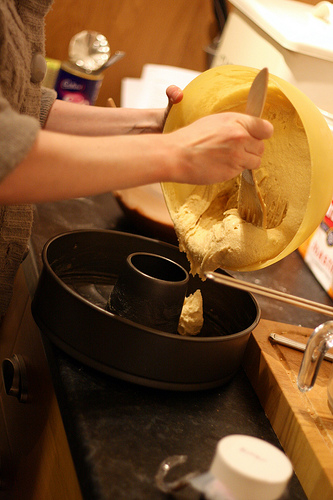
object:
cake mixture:
[173, 85, 311, 334]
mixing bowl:
[158, 61, 332, 272]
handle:
[296, 317, 332, 392]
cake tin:
[30, 227, 262, 394]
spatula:
[236, 66, 269, 231]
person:
[0, 0, 274, 208]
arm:
[0, 98, 274, 203]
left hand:
[160, 85, 187, 128]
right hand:
[168, 109, 274, 187]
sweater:
[0, 1, 59, 320]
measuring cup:
[187, 433, 296, 499]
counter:
[21, 187, 332, 499]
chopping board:
[244, 313, 333, 498]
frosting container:
[53, 25, 110, 107]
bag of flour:
[297, 199, 332, 297]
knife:
[267, 331, 333, 367]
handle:
[150, 452, 200, 486]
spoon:
[99, 49, 126, 72]